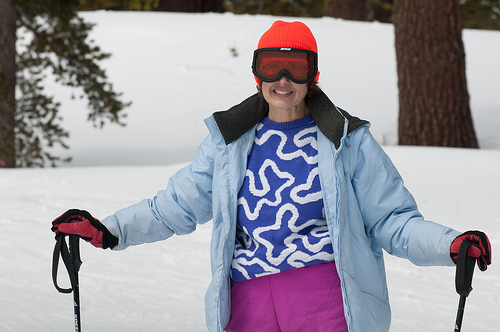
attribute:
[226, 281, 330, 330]
these — pants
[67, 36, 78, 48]
these — leaves